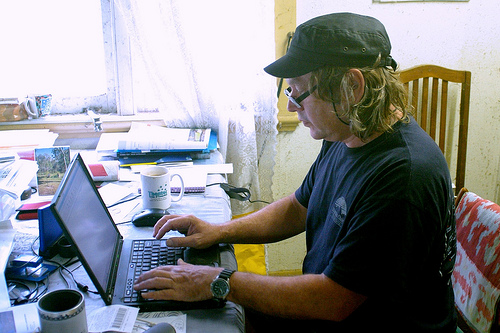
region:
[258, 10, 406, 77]
this man is wearing a black cap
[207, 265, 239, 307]
this man is wearing a watch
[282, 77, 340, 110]
this man wears glasses perched forward on his nose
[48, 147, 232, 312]
this man is working at a laptop computer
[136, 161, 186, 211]
this man has a coffee cup to his right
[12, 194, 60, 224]
this man's wallet is sitting on the desk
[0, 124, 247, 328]
this man's desk is pretty messy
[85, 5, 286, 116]
it looks like a sunny day outside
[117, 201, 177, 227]
this man has a corded mouse on the desk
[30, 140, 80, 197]
a photograph on a little stand sits on the desk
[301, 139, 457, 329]
Man wearing black tees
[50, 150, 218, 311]
Man working on laptop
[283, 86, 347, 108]
Man wearing spectacles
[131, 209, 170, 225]
Mouse lying near laptop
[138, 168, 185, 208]
Coffee mug kept near mouse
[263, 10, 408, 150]
Man wearing black cap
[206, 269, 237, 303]
Man wearing wrist watch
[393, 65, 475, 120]
Wooden chair close to wall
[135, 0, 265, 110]
Screen near window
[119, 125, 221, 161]
Books kept over table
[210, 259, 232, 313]
silver and grey wrist watch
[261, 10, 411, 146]
mean wearing a black ball cap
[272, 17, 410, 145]
man wearing black framed reading glasses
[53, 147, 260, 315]
man typing on a laptop computer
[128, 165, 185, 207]
white porcelin coffee mug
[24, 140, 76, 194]
framed photo of a few trees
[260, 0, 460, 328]
man wearing a black t-shirt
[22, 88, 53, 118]
white decorated coffe mug sitting on a windowsill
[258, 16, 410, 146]
man with dishwater blond hair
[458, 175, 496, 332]
red and grey patterned blanket draped over a chair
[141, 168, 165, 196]
a cup on the table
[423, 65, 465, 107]
a wooden chair in the back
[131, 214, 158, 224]
a computer mouse on the table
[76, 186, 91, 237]
the screen of a laptop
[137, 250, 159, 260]
the keyboard of a laptop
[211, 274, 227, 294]
a wrist watch on the man's hand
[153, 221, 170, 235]
fingers of the man typing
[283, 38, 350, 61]
the cap on head of the man typing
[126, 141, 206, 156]
files on the table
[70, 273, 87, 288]
a laptop's power cable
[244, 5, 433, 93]
Man wearing a hat on his head.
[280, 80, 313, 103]
Man wearing glasses on face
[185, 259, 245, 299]
The man is wearing a watch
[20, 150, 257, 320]
Laptop is open and being typed on.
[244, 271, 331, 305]
Man has hair on his arms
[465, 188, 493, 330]
Back of chair is made of cloth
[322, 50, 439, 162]
Man has medium length hair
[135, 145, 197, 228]
Coffee mug on the table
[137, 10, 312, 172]
Sheer curtain by the window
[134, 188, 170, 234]
Mouse beside the laptop